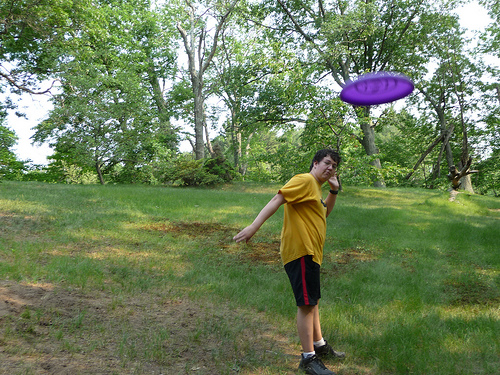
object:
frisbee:
[339, 75, 415, 106]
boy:
[232, 149, 346, 374]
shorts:
[284, 254, 322, 306]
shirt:
[278, 173, 327, 267]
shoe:
[299, 353, 336, 375]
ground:
[0, 289, 138, 372]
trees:
[178, 0, 242, 187]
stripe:
[301, 257, 309, 305]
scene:
[1, 0, 499, 375]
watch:
[329, 189, 339, 195]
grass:
[399, 183, 500, 269]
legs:
[284, 260, 320, 353]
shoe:
[313, 339, 346, 359]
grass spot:
[4, 194, 213, 255]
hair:
[309, 149, 342, 171]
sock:
[313, 337, 325, 347]